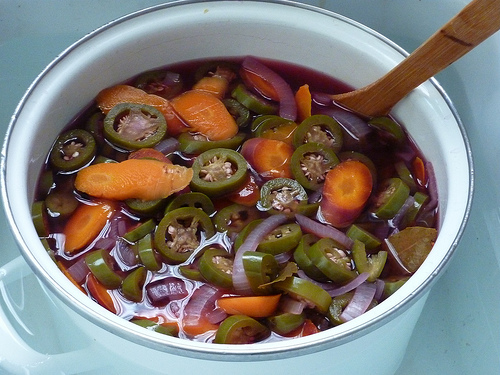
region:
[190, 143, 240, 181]
green pepper in pot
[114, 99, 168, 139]
green pepper in pot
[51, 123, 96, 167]
green pepper in pot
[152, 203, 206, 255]
green pepper in pot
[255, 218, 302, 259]
green pepper in pot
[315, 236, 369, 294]
green pepper in pot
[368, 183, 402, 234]
green pepper in pot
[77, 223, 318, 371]
picture of vegetable soup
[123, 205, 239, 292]
picture of vegetable soup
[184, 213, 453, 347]
picture of vegetable soup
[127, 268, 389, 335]
picture of vegetable soup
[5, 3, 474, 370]
soup inside of crockpot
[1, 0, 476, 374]
crockpot is white and silver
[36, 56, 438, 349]
slices of carrots in soup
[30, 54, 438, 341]
slices of jalapeno in soup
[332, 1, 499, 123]
wood spoon sticking out of soup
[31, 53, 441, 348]
sliced red onions in soup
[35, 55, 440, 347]
vegetable soup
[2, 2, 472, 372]
crockpot holding soup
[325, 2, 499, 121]
wood spoon leaning in crockpot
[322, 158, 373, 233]
chunk of boiled carrot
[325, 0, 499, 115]
a brown wooden spoon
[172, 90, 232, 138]
a slice of orange carrot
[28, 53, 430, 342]
a mixture of various vegetables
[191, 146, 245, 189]
a sliced jalapeno pepper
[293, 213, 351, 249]
a purple onion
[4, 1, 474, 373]
the pot is white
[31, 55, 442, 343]
liquid is in the pot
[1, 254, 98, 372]
a white pot handle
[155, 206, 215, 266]
jalapeno pepper is round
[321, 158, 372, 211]
carrot is orange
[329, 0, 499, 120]
the wooden utensil in the pot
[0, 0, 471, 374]
the large white pot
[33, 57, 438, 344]
the food in the pot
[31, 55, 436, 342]
the liquid in the pot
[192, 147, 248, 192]
the sliced jalapeno in the pot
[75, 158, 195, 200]
the sliced carrot in the pot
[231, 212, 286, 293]
the sliced onion in the pot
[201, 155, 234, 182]
the seeds in the jalapeno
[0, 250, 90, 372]
the handle of the pot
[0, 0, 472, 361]
the silver rim on the pot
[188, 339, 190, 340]
picture of vegetable soup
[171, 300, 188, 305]
picture of vegetable soup